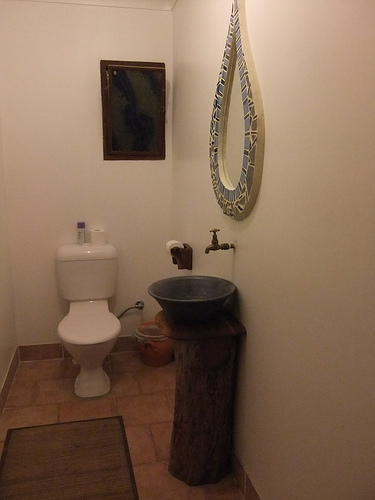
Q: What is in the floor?
A: Mat.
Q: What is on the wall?
A: Mirror.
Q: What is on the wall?
A: Art.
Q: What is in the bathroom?
A: Toilet.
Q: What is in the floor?
A: Rug.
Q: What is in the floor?
A: Carpet.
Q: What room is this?
A: A bathroom.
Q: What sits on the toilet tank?
A: Tissue paper and air freshner.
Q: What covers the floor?
A: An area rug.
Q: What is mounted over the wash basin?
A: A mirror.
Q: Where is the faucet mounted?
A: Over the wash basin.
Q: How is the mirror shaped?
A: Tear shaped.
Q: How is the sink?
A: Rustic styled.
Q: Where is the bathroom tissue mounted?
A: It is mounted on the wall opposite the toilet.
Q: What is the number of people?
A: Zero people.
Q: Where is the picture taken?
A: A bathroom.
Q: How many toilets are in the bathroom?
A: One.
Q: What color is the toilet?
A: White.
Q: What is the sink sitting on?
A: A log.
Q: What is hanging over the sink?
A: A mirror.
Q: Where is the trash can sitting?
A: On the floor.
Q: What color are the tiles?
A: Brown.